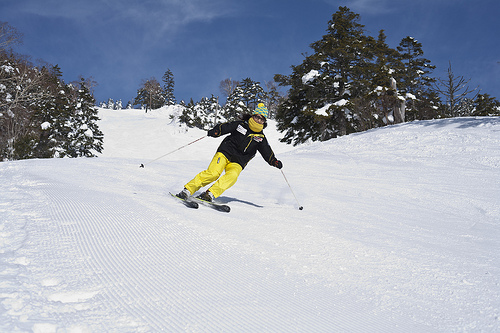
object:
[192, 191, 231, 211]
skis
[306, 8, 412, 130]
tree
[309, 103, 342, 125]
snow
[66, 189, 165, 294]
ground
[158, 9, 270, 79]
sky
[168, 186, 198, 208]
skis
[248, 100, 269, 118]
cap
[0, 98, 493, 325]
slope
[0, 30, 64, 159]
trees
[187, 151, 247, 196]
pants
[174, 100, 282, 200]
skier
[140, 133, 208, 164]
ski poles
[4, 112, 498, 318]
mountain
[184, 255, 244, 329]
lines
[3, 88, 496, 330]
snow